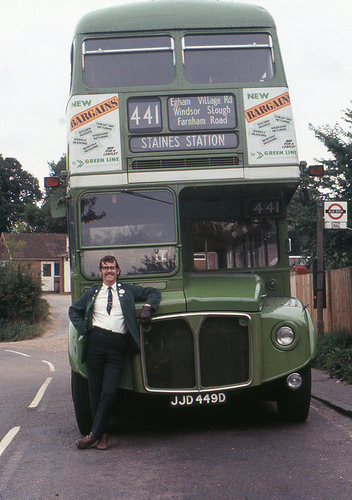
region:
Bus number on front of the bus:
[126, 94, 165, 132]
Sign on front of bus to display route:
[164, 90, 239, 130]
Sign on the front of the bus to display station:
[126, 132, 239, 150]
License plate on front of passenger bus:
[167, 393, 231, 409]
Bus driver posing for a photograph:
[61, 256, 158, 452]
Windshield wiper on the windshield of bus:
[116, 188, 176, 213]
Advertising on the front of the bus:
[243, 85, 298, 163]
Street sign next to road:
[322, 197, 347, 229]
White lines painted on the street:
[20, 366, 59, 421]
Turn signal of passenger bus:
[35, 167, 64, 193]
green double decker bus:
[47, 13, 297, 288]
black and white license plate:
[154, 389, 260, 423]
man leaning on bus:
[51, 233, 168, 454]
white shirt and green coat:
[69, 264, 169, 342]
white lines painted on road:
[4, 339, 57, 455]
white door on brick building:
[29, 244, 66, 304]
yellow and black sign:
[61, 98, 122, 122]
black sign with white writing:
[130, 122, 256, 155]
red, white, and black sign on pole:
[312, 193, 347, 320]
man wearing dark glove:
[76, 239, 166, 335]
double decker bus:
[33, 17, 333, 431]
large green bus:
[2, 9, 301, 498]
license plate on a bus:
[87, 389, 251, 437]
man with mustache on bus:
[1, 256, 172, 466]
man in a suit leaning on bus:
[26, 243, 177, 454]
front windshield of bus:
[57, 160, 291, 292]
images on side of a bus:
[36, 63, 293, 207]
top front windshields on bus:
[31, 8, 303, 119]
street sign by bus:
[243, 188, 350, 252]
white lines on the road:
[0, 330, 70, 470]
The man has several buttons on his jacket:
[70, 253, 153, 314]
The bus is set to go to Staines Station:
[119, 129, 250, 158]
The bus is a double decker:
[53, 1, 325, 295]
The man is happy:
[61, 252, 172, 369]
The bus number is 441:
[121, 97, 166, 134]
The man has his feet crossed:
[52, 314, 154, 469]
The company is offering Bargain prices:
[59, 92, 124, 170]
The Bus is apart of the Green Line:
[67, 149, 130, 176]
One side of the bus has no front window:
[172, 179, 314, 288]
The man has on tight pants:
[73, 300, 133, 448]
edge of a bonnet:
[216, 288, 246, 302]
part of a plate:
[196, 390, 223, 403]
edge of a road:
[330, 402, 345, 424]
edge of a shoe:
[72, 440, 83, 452]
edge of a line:
[27, 395, 44, 421]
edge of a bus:
[234, 373, 262, 392]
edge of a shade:
[189, 422, 214, 441]